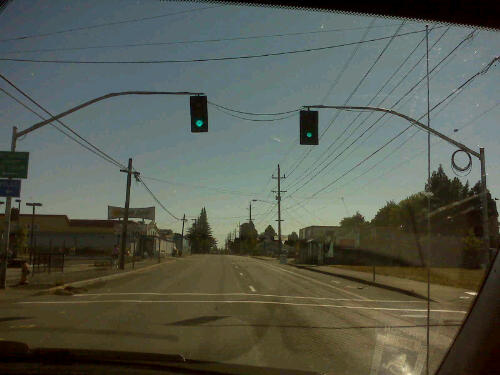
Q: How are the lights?
A: The lights are green.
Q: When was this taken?
A: During the day time.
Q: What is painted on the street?
A: Lines.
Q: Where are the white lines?
A: On the road.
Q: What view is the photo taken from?
A: Inside the car.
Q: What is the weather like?
A: Clear skies.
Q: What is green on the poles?
A: Street lights.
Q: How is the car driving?
A: Straight.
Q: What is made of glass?
A: The window.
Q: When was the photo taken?
A: Daytime.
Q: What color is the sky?
A: Blue.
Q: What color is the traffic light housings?
A: Black.